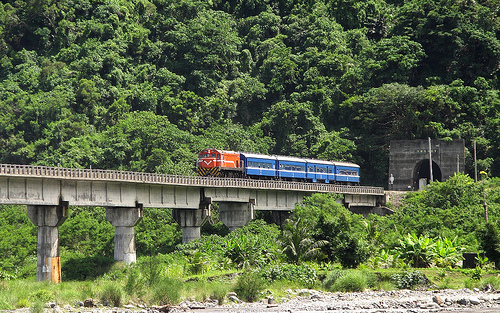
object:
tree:
[286, 191, 367, 261]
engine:
[196, 147, 244, 177]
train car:
[240, 152, 276, 179]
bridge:
[0, 162, 384, 288]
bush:
[360, 233, 460, 268]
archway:
[410, 157, 442, 191]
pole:
[36, 206, 61, 283]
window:
[248, 161, 253, 167]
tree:
[163, 6, 249, 97]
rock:
[431, 294, 448, 306]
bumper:
[197, 166, 220, 177]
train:
[198, 147, 361, 185]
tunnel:
[387, 138, 467, 191]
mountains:
[3, 1, 39, 24]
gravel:
[0, 286, 500, 312]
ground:
[2, 233, 500, 313]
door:
[50, 256, 62, 284]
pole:
[427, 136, 433, 184]